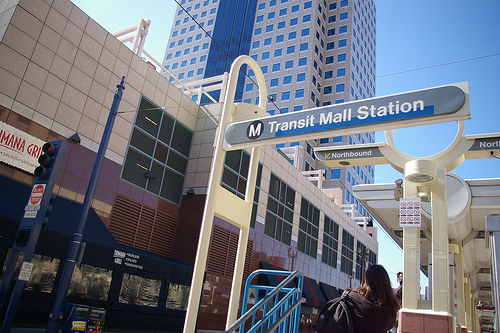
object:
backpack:
[311, 287, 356, 332]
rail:
[220, 267, 309, 332]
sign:
[22, 183, 47, 219]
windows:
[285, 44, 295, 55]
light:
[32, 140, 61, 184]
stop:
[42, 142, 56, 155]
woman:
[310, 262, 402, 332]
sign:
[221, 79, 474, 154]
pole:
[181, 52, 270, 333]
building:
[159, 0, 380, 222]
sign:
[0, 118, 51, 176]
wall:
[0, 0, 151, 232]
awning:
[0, 173, 209, 287]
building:
[0, 0, 381, 333]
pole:
[43, 73, 129, 333]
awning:
[255, 259, 345, 310]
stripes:
[304, 276, 319, 308]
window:
[118, 272, 165, 309]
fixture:
[403, 159, 437, 185]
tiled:
[0, 0, 380, 293]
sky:
[68, 0, 500, 191]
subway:
[220, 62, 499, 333]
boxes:
[59, 313, 94, 333]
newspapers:
[96, 314, 100, 315]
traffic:
[0, 170, 402, 332]